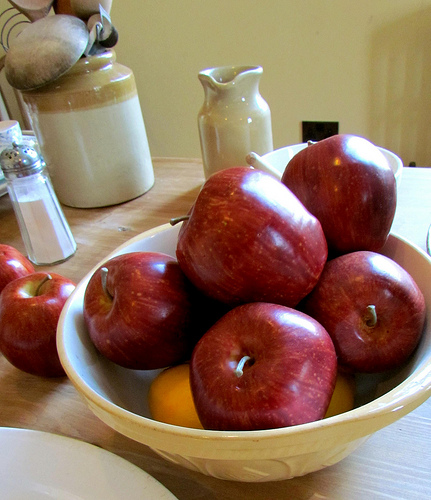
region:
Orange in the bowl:
[149, 362, 216, 432]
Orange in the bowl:
[317, 370, 363, 416]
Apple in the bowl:
[187, 304, 339, 430]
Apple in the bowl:
[311, 250, 427, 370]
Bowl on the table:
[58, 205, 428, 466]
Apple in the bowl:
[281, 146, 404, 253]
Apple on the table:
[0, 271, 81, 387]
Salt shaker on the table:
[2, 141, 80, 265]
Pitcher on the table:
[183, 59, 290, 180]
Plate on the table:
[1, 409, 187, 499]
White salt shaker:
[0, 140, 77, 265]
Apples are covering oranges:
[79, 251, 389, 423]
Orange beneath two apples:
[140, 368, 204, 428]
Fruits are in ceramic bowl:
[50, 203, 429, 483]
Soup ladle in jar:
[4, 12, 95, 95]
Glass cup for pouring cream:
[194, 61, 275, 180]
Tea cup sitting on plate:
[0, 113, 43, 189]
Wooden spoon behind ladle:
[7, 0, 54, 20]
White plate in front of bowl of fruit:
[2, 423, 175, 498]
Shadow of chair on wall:
[363, 13, 429, 162]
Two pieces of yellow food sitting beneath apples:
[148, 361, 356, 428]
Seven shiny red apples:
[0, 133, 427, 428]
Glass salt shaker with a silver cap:
[1, 143, 76, 266]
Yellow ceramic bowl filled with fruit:
[52, 211, 428, 486]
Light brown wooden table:
[2, 154, 429, 498]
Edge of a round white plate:
[2, 425, 181, 498]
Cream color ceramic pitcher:
[194, 61, 273, 182]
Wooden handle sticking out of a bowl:
[244, 137, 403, 187]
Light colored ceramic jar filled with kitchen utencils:
[16, 33, 155, 207]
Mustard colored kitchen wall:
[122, 32, 429, 168]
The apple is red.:
[0, 271, 76, 386]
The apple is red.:
[80, 242, 201, 377]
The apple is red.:
[184, 293, 339, 433]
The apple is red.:
[312, 240, 424, 377]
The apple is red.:
[160, 154, 329, 309]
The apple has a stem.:
[0, 269, 81, 387]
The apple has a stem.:
[81, 244, 211, 375]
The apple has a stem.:
[184, 297, 337, 435]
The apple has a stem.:
[302, 240, 427, 380]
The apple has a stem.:
[165, 160, 330, 310]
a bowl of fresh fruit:
[54, 133, 428, 481]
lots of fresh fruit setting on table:
[0, 133, 424, 432]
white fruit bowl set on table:
[55, 215, 429, 480]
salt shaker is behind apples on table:
[0, 143, 75, 263]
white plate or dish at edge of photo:
[0, 429, 177, 498]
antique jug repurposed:
[22, 47, 154, 205]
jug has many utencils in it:
[0, 0, 154, 206]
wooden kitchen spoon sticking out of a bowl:
[245, 137, 401, 181]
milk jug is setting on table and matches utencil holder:
[197, 64, 270, 179]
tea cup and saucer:
[0, 121, 36, 193]